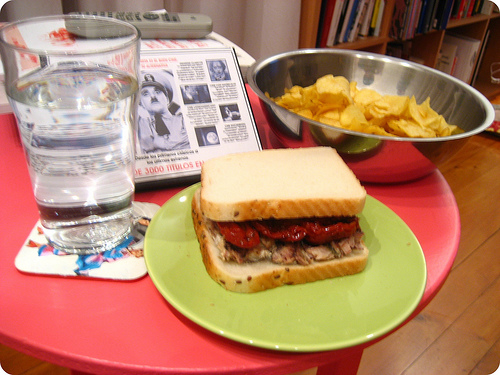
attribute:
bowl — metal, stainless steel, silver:
[249, 41, 494, 181]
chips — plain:
[276, 65, 445, 140]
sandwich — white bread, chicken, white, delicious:
[193, 142, 368, 300]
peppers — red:
[216, 216, 360, 245]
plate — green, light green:
[138, 180, 429, 353]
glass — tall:
[11, 18, 151, 252]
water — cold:
[12, 74, 129, 235]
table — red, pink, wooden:
[2, 60, 466, 374]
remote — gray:
[66, 4, 221, 38]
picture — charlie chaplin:
[139, 67, 186, 150]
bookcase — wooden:
[302, 4, 499, 96]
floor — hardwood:
[361, 128, 498, 373]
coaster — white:
[19, 198, 161, 284]